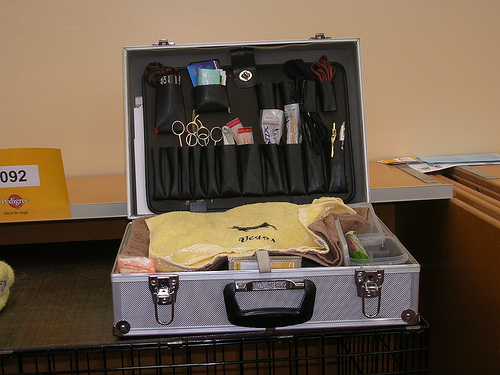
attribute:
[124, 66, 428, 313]
briefcase — silver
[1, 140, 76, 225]
sign — yellow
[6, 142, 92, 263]
sign — yellow